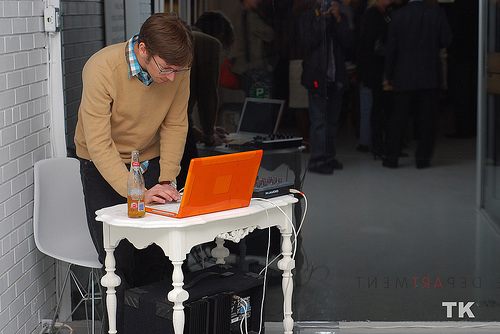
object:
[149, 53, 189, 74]
eye glasses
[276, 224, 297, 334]
leg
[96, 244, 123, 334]
leg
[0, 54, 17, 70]
brick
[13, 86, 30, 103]
brick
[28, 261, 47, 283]
brick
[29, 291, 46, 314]
brick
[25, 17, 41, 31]
brick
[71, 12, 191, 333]
man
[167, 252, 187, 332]
leg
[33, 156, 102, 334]
chair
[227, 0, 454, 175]
people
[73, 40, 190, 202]
sweater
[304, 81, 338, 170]
jeans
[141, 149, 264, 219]
laptop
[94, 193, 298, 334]
desk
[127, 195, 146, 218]
liquid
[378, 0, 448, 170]
person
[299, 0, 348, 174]
person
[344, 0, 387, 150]
person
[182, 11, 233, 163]
person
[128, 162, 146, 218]
bottle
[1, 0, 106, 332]
brick wall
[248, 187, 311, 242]
cords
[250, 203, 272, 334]
cord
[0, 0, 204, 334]
building